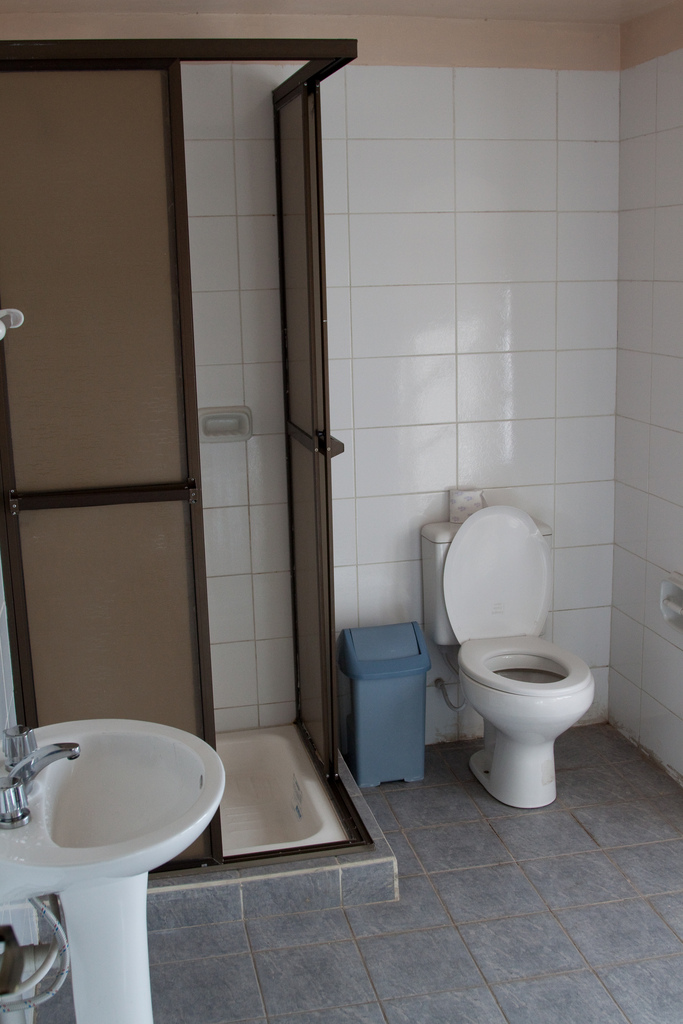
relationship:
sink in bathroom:
[2, 712, 231, 1022] [3, 2, 676, 1019]